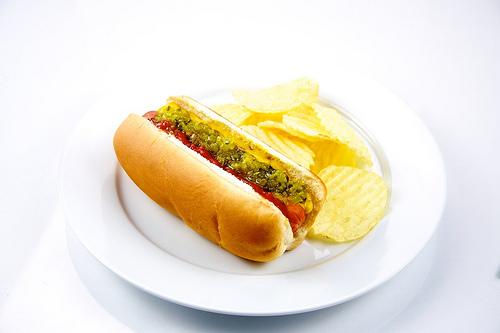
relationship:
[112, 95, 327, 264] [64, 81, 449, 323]
hotdog on plate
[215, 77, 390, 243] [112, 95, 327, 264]
chips are by hotdog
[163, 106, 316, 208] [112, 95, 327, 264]
relish on hotdog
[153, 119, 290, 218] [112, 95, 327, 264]
ketchup on hotdog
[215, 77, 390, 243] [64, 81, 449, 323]
chips are on plate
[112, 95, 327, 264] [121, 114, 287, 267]
hotdog in a bun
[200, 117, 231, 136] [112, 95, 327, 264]
mustard on hotdog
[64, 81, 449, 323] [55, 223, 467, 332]
plate has a shadow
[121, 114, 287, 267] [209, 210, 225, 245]
bun has a line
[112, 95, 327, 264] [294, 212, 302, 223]
hotdog has a line